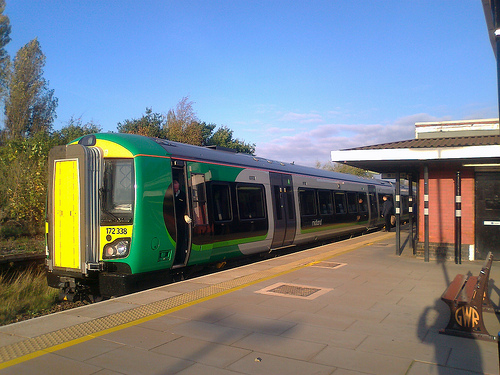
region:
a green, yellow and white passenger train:
[26, 108, 326, 293]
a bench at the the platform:
[430, 242, 498, 349]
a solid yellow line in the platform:
[124, 300, 180, 335]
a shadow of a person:
[406, 283, 479, 371]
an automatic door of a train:
[263, 162, 300, 254]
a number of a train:
[101, 223, 129, 237]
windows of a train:
[191, 179, 271, 227]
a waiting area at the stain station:
[328, 113, 483, 254]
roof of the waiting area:
[393, 135, 443, 147]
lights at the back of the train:
[103, 240, 128, 260]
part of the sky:
[299, 28, 351, 93]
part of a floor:
[354, 293, 392, 331]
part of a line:
[164, 286, 192, 318]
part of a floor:
[349, 283, 385, 322]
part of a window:
[209, 180, 247, 226]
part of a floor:
[361, 280, 391, 318]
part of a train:
[196, 203, 248, 277]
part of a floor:
[277, 249, 320, 283]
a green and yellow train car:
[43, 134, 395, 304]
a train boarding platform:
[0, 224, 498, 373]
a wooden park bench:
[433, 251, 496, 343]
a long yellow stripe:
[0, 229, 394, 374]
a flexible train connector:
[46, 145, 101, 279]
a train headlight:
[114, 241, 126, 256]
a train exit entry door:
[264, 170, 298, 251]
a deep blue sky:
[2, 0, 497, 162]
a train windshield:
[98, 157, 135, 220]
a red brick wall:
[416, 172, 473, 246]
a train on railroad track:
[29, 124, 396, 297]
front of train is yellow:
[31, 128, 144, 288]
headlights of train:
[35, 234, 137, 261]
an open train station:
[12, 120, 499, 372]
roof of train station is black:
[321, 128, 498, 171]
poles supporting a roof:
[388, 169, 475, 268]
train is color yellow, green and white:
[26, 123, 383, 286]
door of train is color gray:
[260, 169, 307, 254]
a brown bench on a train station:
[433, 248, 499, 343]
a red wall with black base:
[408, 172, 483, 262]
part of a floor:
[256, 302, 296, 361]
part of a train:
[125, 198, 186, 292]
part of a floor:
[306, 290, 335, 322]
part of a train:
[184, 201, 220, 252]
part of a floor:
[341, 294, 381, 350]